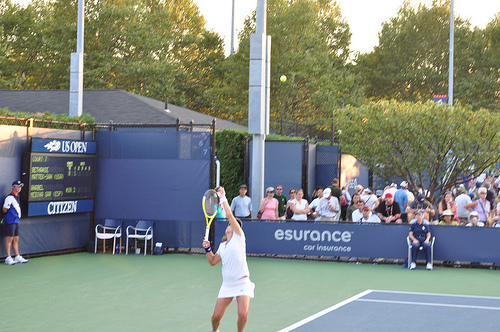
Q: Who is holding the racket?
A: Player.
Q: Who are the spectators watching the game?
A: Fans.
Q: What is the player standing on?
A: Tennis court.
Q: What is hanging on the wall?
A: Scoreboard.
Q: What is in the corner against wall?
A: Chairs.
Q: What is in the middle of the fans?
A: Tree.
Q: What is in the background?
A: Trees.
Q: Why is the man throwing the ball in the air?
A: To hit it.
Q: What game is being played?
A: Tennis.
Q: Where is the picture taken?
A: Tennis court.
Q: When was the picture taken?
A: During a tennis game.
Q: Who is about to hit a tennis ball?
A: A player.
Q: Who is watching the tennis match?
A: Crowd of people.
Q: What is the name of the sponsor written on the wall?
A: Esurance.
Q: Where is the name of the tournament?
A: Scoreboard.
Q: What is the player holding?
A: Tennis racquet.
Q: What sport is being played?
A: Tennis.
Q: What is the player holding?
A: Tennis racket.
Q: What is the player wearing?
A: White blouse and skirt.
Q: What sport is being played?
A: Tennis.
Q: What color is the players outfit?
A: White.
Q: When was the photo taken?
A: During the daytime.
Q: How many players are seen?
A: One.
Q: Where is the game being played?
A: On a tennis court.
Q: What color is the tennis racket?
A: Yellow.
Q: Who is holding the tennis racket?
A: The tennis player.